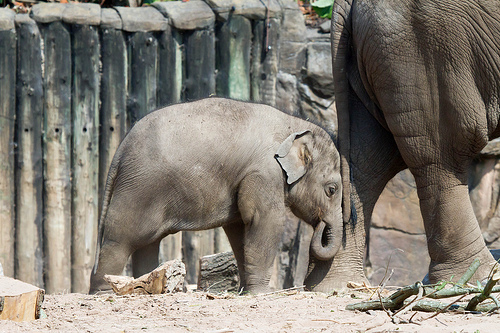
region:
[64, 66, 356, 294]
a baby elephant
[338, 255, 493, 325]
tree branches on the ground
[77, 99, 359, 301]
a baby elephant leaning on another elephant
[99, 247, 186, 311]
a piece of wood on the ground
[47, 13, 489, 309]
a young elephant behind a larger one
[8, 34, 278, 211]
a wooden fence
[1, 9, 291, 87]
rocks atop a wooden fence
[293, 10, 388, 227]
the tail of a elephant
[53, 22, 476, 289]
two elephants next to each other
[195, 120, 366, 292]
a baby elephant with its trunk curled up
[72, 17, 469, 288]
A baby elephant with a mother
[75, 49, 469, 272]
Two grey elepants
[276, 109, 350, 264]
The head of a baby elephant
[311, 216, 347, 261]
The trunk of a baby elephant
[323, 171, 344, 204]
The eye of a baby elephant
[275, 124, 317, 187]
The ear of a baby elephant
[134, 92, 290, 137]
The back of a baby elephant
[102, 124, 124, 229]
The tail of a baby elephant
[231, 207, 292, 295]
The leg of a baby elephant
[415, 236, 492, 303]
The foot of a big elephant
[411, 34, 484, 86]
rough wrinkled gray skin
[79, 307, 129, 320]
rocks scattered on the ground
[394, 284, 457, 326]
a tree branch on the ground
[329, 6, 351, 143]
a tail hanging on a backside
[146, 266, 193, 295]
large stones on the ground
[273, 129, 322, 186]
a flappy ear on a head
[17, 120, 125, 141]
holes drilled in the fence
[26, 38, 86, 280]
a wooden fence enclosing the elephants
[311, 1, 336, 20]
a green leaf on a tree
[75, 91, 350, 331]
a baby elephant nodging it's mother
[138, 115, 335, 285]
this is a calf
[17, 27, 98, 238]
this are wooden barrier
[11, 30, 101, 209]
the wooden barrier is black in color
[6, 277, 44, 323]
this is a piece of wood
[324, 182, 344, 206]
this the eyes of a calf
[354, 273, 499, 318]
this is a broken branch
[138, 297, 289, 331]
this the ground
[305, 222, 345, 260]
this is the calf trunk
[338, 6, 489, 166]
this is an elephant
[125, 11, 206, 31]
these are stone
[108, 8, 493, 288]
these are two elephants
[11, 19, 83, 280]
this is a fence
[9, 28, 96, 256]
the fence is made of wood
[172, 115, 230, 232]
the skin is smooth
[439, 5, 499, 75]
the skin is wrinkled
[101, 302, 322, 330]
this is the ground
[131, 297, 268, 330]
the ground is sandy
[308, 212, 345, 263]
the trunk is folded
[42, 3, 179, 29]
these are some rocks